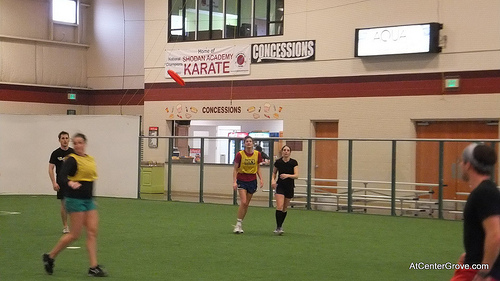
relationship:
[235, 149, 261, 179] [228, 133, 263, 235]
yellow tank on man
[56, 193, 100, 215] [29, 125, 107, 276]
shorts on woman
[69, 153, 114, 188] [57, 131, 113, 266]
yellow shirt on woman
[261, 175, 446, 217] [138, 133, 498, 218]
bleachers behind fence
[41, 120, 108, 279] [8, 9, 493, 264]
people at gym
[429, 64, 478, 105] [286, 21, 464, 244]
exit on wall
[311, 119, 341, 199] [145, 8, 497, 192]
door on wall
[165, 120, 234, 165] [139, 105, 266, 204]
window on wall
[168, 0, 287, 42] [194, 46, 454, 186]
window on wall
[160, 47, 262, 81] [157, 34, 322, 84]
sign on wall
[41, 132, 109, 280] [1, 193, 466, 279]
people running on floor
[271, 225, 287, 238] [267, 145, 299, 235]
shoes of people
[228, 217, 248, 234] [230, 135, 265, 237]
shoes of woman